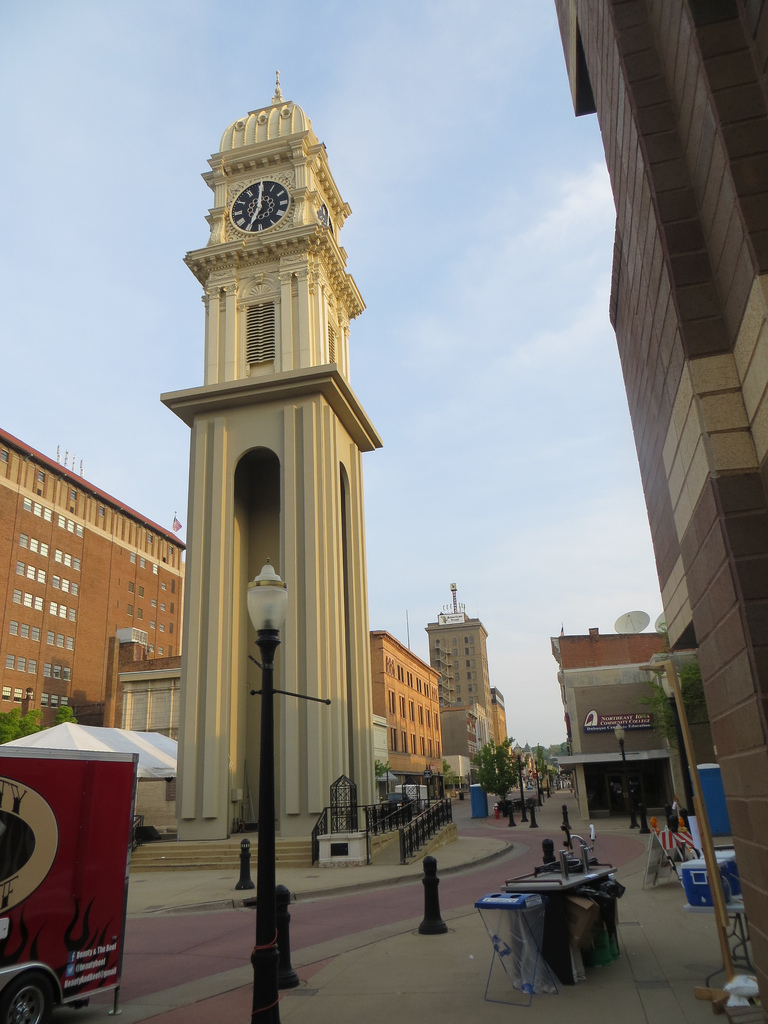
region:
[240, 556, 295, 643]
the light is off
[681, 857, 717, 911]
the cooler is sitting on the sidewalk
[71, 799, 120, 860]
the trailer is red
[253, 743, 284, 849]
the pole is black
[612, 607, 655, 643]
the satellite dish is on the roof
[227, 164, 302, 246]
the clock is at the top of the tower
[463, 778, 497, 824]
the porta pot is blue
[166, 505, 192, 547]
the flag is on the roof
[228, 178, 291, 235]
A clock on a tower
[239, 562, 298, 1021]
A light post in a city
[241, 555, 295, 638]
A lamp on a post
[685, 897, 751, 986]
A white table in a city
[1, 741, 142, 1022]
A red trailer parked on sidewalk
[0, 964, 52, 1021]
A tire on a trailer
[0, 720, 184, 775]
A tent near a clock tower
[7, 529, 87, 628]
Windows on the side of a building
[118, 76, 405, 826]
tan and black clock tower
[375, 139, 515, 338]
blue and white sky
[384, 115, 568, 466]
white clouds in sky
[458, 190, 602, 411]
thin clouds in sky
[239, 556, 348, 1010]
light on black pole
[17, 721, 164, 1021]
red truck is parked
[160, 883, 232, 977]
red brick on street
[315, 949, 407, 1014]
sidewalk is light brown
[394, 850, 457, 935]
black pylon near road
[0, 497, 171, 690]
building is red brick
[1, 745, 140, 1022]
a yellow truck with food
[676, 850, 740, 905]
a blue water cooler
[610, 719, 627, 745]
a street light on the side of the street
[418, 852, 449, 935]
a metal pole on the street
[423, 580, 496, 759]
a tan tall thin building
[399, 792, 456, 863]
a railing on a pathway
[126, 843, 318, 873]
the steps in front of a tower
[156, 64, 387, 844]
Tall beige clocktower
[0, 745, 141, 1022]
parked red trailer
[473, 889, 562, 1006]
Blue recycling can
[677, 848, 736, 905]
blue and white cooler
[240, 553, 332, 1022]
Lamp post next to trailer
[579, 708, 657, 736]
Red, blue, and white sign on building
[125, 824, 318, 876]
stone steps leading to clocktower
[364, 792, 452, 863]
ramp leading up to clocktower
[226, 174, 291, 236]
dark circular clock face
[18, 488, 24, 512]
a window on a building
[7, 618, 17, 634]
a window on a building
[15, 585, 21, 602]
a window on a building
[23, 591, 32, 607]
a window on a building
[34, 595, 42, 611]
a window on a building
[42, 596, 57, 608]
a window on a building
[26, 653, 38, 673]
a window on a building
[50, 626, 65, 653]
a window on a building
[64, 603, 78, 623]
a window on a building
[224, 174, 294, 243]
large clock on top of tan tower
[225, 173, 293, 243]
large clock with black face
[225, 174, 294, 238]
black face of large clock with white numerals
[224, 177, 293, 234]
black face of large clock with white hands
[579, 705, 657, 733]
red sign with white letters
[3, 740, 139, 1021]
rear portion of red delivery van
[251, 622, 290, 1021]
tall black post on the sidewalk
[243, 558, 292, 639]
white light with gold trim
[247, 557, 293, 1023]
white street light on top of black pole